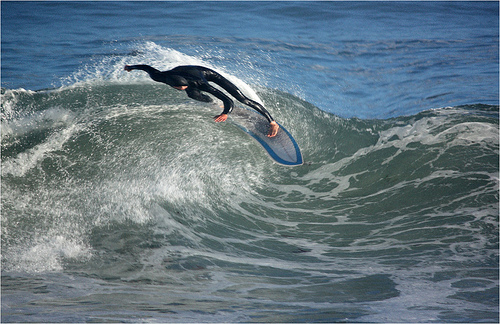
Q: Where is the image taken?
A: In water.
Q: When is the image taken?
A: Riding.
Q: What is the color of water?
A: Blue.